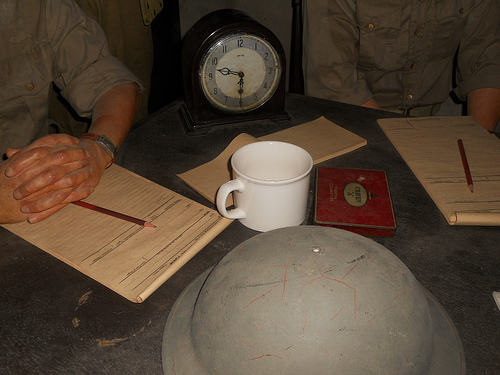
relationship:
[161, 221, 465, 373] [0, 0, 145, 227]
grey hat of he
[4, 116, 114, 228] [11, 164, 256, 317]
hands on paper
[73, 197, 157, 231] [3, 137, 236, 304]
pencil with form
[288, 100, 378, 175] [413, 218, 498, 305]
paper on table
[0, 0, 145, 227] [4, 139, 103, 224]
he interlocked fingers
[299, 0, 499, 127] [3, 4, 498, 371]
person in room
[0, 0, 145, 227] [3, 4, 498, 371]
he in room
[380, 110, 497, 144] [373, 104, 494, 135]
hands on lap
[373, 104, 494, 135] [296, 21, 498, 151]
lap of person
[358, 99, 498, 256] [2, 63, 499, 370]
paper on table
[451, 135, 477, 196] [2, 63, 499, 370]
pencil on table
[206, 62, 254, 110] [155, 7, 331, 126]
9: 30 on clock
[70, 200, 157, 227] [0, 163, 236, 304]
pencil on form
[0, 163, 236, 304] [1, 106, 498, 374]
form on table top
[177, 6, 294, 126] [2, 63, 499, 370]
clock on table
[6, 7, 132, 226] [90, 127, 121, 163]
he wearing a watch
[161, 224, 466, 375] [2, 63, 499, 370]
grey hat on table